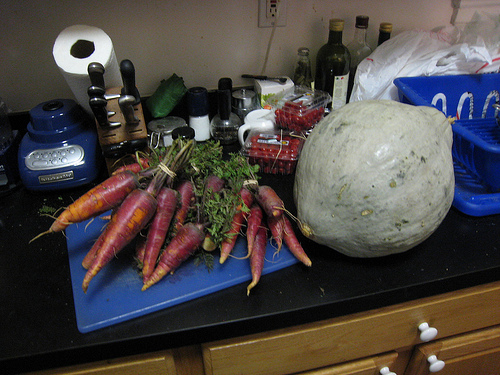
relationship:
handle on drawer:
[417, 321, 439, 343] [205, 289, 499, 369]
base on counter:
[16, 91, 94, 200] [5, 61, 498, 368]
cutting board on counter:
[60, 171, 302, 330] [5, 61, 498, 368]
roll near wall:
[47, 14, 138, 111] [7, 0, 499, 114]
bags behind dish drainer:
[347, 12, 498, 103] [391, 71, 500, 219]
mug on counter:
[238, 106, 278, 146] [5, 61, 498, 368]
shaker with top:
[187, 83, 214, 150] [186, 86, 211, 119]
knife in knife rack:
[90, 95, 114, 134] [95, 79, 149, 173]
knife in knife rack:
[122, 93, 140, 133] [95, 79, 149, 173]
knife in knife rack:
[86, 63, 108, 93] [95, 79, 149, 173]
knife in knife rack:
[114, 57, 145, 102] [95, 79, 149, 173]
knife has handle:
[90, 95, 114, 134] [91, 96, 109, 127]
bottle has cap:
[312, 16, 357, 110] [331, 16, 346, 32]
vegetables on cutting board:
[25, 139, 313, 299] [60, 171, 302, 330]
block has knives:
[89, 78, 149, 172] [83, 55, 150, 136]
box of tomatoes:
[268, 82, 332, 130] [275, 98, 323, 129]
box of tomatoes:
[242, 128, 301, 176] [248, 136, 299, 174]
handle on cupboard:
[425, 361, 449, 374] [409, 319, 500, 367]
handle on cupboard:
[417, 326, 441, 343] [208, 287, 499, 374]